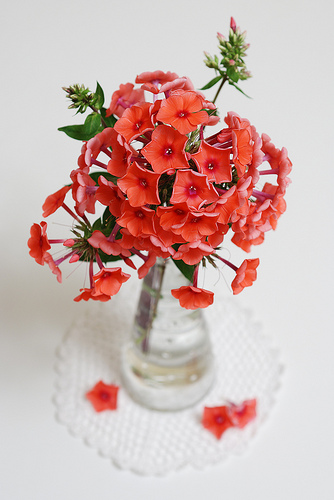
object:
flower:
[81, 377, 120, 413]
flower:
[199, 402, 237, 441]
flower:
[227, 397, 258, 429]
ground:
[0, 268, 332, 496]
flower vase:
[118, 251, 219, 414]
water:
[119, 256, 218, 413]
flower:
[154, 92, 210, 136]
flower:
[170, 284, 214, 311]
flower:
[231, 257, 261, 296]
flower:
[169, 166, 211, 211]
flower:
[90, 267, 132, 298]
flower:
[27, 220, 52, 267]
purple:
[188, 185, 197, 196]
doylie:
[52, 268, 285, 478]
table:
[0, 0, 332, 499]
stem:
[203, 78, 227, 131]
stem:
[135, 261, 167, 345]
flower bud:
[65, 92, 79, 101]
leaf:
[91, 79, 105, 112]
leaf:
[82, 112, 103, 136]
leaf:
[56, 123, 102, 141]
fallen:
[198, 405, 237, 441]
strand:
[211, 252, 238, 273]